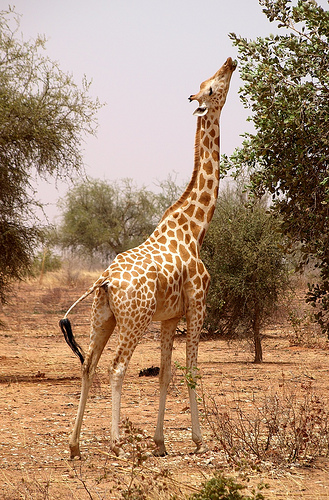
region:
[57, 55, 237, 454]
the giraffe standing on the dirt in a field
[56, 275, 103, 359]
the skinny tail at the back of the giraffe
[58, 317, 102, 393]
the black hair at the end of the giraffe's tail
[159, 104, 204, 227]
the mane on the back of the giraffe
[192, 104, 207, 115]
the right ear on the giraffe's head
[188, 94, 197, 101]
the horns on the top of the giraffe's head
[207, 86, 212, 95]
the right eye on the giraffe's head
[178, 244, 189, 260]
the brown spot on the giraffe's body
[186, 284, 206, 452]
the giraffe's front right leg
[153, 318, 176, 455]
the giraffe's front left leg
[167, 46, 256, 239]
the giraffe is looking up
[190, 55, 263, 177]
the giraffe is looking up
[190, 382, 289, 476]
the branches are bare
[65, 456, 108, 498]
the branches are bare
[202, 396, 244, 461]
the branches are bare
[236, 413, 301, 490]
the branches are bare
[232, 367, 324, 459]
the branches are bare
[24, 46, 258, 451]
spotted giraffe standing in dirt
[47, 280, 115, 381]
tail of giraffe with bushy end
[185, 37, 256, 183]
giraffe stretching neck to eat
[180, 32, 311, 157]
giraffe craning neck to eat leaves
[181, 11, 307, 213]
giraffe eating leaves on trees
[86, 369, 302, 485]
dirt and dried plants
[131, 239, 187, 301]
brown and white spots on giraffe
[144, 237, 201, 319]
orange and white spots on giraffe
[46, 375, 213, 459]
white legs of giraffe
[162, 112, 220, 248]
short fringe on giraffe neck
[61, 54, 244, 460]
The giraffe is standing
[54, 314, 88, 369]
The giraffe has a black tail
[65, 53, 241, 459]
The giraffe is spotted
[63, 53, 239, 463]
The giraffe is brown and white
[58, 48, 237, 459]
The giraffe is eating the leaves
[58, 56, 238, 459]
The giraffe is grazing on the tree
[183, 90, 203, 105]
The giraffe has small horns on its head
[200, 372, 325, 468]
Brown bush with brown leaves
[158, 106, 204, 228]
The giraffe has a short mane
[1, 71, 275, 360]
Trees behind the giraffe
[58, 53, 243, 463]
this is a giraffe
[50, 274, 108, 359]
the tail of a girafffe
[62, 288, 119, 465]
the leg of a girafffe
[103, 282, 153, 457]
the leg of a girafffe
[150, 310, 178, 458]
the leg of a girafffe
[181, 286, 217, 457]
the leg of a girafffe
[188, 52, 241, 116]
the head of a girafffe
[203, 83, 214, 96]
the eye of a girafffe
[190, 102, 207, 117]
the ear of a girafffe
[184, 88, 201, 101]
the horn of a girafffe